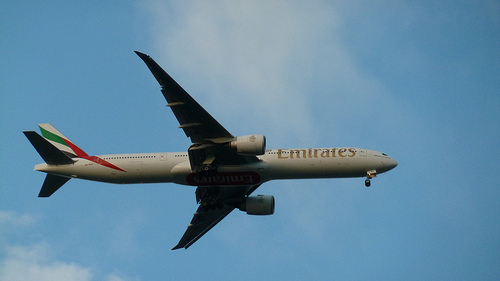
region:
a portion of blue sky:
[387, 20, 478, 111]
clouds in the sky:
[200, 9, 324, 84]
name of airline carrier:
[279, 145, 364, 167]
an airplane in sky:
[18, 40, 410, 253]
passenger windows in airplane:
[112, 154, 177, 161]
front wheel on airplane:
[362, 170, 389, 198]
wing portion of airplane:
[132, 47, 241, 136]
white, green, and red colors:
[36, 119, 120, 168]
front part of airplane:
[366, 145, 398, 175]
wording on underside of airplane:
[184, 172, 261, 190]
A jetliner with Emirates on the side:
[22, 49, 397, 249]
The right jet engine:
[220, 134, 267, 156]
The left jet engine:
[228, 192, 274, 217]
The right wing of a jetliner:
[140, 50, 265, 169]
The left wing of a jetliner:
[167, 180, 269, 251]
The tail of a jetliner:
[23, 123, 90, 197]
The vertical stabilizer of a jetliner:
[39, 119, 89, 159]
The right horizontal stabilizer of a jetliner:
[22, 130, 76, 165]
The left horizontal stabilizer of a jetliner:
[38, 170, 75, 196]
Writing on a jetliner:
[278, 146, 358, 159]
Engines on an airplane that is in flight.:
[231, 132, 276, 217]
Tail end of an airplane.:
[21, 121, 88, 200]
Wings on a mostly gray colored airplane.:
[133, 51, 255, 249]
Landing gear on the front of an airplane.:
[363, 171, 373, 186]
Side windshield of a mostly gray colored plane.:
[381, 152, 388, 156]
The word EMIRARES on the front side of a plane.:
[273, 144, 358, 158]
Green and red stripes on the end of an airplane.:
[38, 126, 126, 173]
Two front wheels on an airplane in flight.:
[363, 177, 370, 186]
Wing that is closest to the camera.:
[133, 48, 238, 165]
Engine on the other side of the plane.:
[226, 190, 278, 218]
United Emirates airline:
[259, 135, 386, 167]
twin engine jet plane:
[155, 108, 326, 256]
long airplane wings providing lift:
[118, 30, 302, 168]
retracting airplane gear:
[354, 156, 419, 221]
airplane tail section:
[0, 105, 128, 235]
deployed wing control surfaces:
[143, 68, 228, 146]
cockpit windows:
[362, 130, 429, 202]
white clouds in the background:
[194, 0, 411, 154]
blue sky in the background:
[19, 0, 116, 97]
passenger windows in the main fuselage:
[113, 146, 187, 163]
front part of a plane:
[393, 162, 397, 169]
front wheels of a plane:
[363, 175, 369, 188]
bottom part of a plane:
[326, 171, 335, 178]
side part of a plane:
[290, 150, 310, 156]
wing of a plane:
[168, 82, 182, 109]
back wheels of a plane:
[203, 202, 216, 212]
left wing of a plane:
[199, 212, 214, 230]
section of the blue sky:
[402, 201, 431, 238]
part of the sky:
[343, 20, 396, 76]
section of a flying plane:
[194, 161, 248, 178]